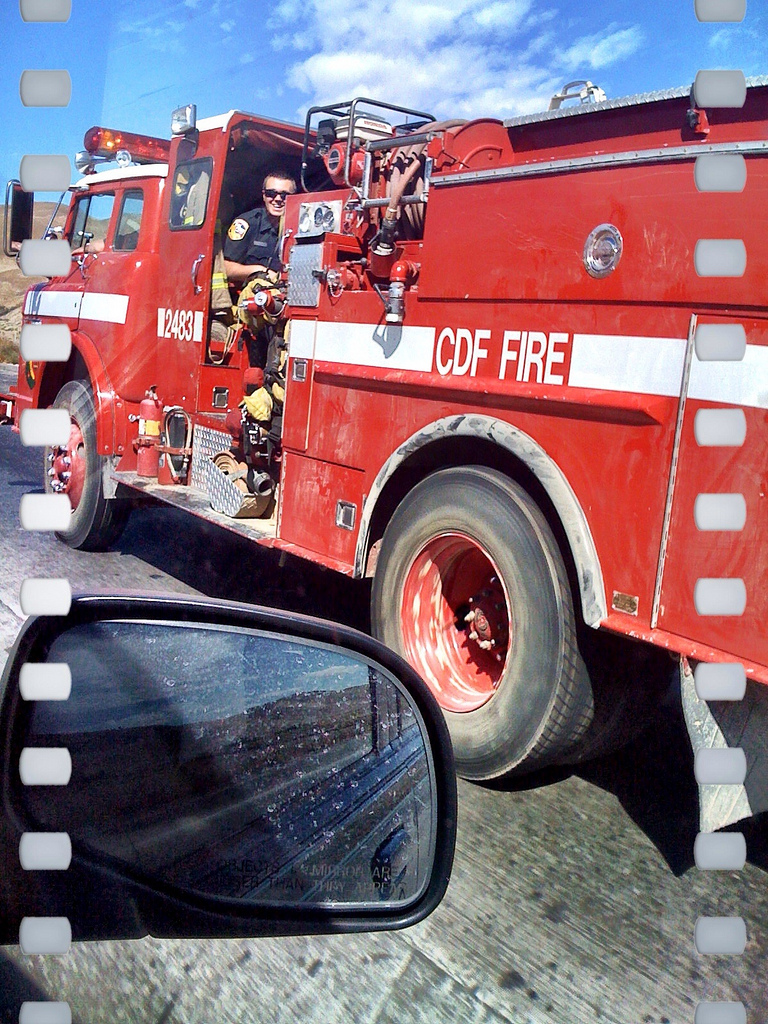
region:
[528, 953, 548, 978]
The woman is holding a large orange.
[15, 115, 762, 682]
a red and white fire truck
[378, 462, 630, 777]
a tire with a red rim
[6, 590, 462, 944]
the side view mirror on a vehicle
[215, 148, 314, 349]
a firefighter sitting in a fire truck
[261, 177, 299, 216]
a man wearing black sunglasses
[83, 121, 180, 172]
a red emergency light on a vehicle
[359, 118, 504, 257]
a fire hose on a reel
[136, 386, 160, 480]
a red and yellow fire extinguisher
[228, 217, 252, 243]
a yellow patch on clothing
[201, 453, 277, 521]
a rolled up fire hose in a metal holder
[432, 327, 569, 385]
white writing on truck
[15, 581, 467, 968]
side view mirror on car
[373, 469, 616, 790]
black tire on truck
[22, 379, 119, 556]
front black tire on truck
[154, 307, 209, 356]
white numbers on truck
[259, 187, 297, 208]
glasses on the man's face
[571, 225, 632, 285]
gas tank on truck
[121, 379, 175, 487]
fire extinguisher on truck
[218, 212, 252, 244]
patch on the man's sleeve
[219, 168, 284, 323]
Man sitting on the back of the fire truck.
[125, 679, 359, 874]
Reflection of the road in the mirror.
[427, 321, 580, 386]
White letters painted on the side of the truck.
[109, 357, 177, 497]
Fire extinguisher on the side of the truck.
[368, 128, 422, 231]
Red water hose wrapped around the truck.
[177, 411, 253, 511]
Silver tool kit on the side of the truck.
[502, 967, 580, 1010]
Black oil stains on the ground.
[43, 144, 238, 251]
Three windows on the side of a red truck.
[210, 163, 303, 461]
man on the back of a firetruck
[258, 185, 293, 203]
sunglasses on a fireman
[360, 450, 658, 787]
back tires of a firetruck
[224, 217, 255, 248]
patch on a man's shoulder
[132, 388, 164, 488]
fire extinguisher on a truck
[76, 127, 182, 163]
light on the top of a firetruck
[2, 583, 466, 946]
rear view mirror on a passenger car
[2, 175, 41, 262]
rear view mirror on a firetruck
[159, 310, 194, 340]
number on a firetruck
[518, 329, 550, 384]
A letter on a car.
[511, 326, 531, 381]
A letter on a car.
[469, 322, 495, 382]
A letter on a car.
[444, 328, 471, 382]
A letter on a car.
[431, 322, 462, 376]
A letter on a car.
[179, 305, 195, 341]
A letter on a car.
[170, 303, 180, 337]
A letter on a car.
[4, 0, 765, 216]
white clouds in blue sky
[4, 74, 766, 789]
side of red fire truck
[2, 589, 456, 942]
reflection on sideview mirror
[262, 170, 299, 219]
man wearing sunglasses on face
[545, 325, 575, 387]
A letter on a firetruck.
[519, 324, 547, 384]
A letter on a firetruck.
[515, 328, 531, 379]
A letter on a firetruck.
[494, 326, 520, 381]
A letter on a firetruck.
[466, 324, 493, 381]
A letter on a firetruck.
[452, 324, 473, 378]
A letter on a firetruck.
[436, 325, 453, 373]
A letter on a firetruck.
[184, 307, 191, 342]
A letter on a firetruck.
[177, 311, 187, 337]
A letter on a firetruck.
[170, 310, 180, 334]
A letter on a firetruck.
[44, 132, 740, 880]
these are fire trucks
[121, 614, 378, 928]
this is a side mirror